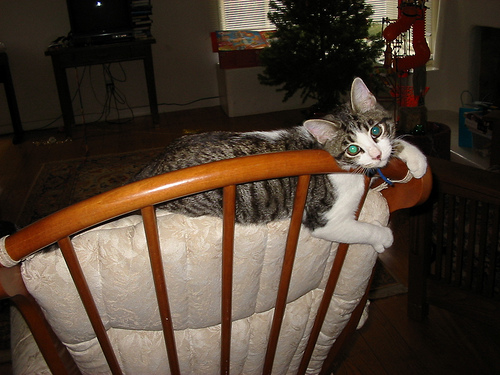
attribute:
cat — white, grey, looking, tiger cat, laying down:
[134, 74, 425, 250]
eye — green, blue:
[344, 142, 362, 156]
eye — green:
[371, 123, 382, 136]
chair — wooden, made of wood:
[6, 141, 428, 374]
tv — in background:
[67, 1, 132, 39]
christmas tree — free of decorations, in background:
[259, 1, 390, 109]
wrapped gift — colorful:
[211, 28, 272, 52]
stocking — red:
[382, 1, 415, 42]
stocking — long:
[390, 9, 438, 65]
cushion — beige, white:
[0, 186, 388, 374]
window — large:
[219, 0, 441, 75]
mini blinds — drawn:
[220, 1, 403, 57]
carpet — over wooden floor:
[2, 103, 493, 341]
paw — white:
[398, 140, 429, 180]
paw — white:
[369, 220, 391, 253]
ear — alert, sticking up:
[351, 77, 375, 111]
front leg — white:
[309, 212, 391, 252]